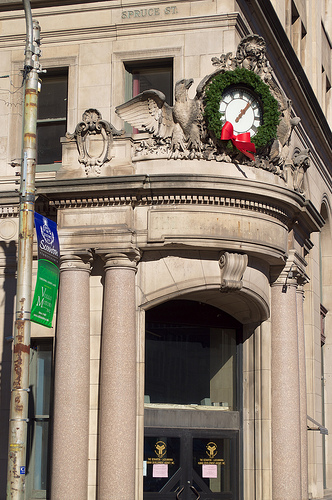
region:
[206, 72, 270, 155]
Christmas wreath on clock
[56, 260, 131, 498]
columns on the building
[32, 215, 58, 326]
blue and green banners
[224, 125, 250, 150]
red bow on wreath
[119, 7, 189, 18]
name of the street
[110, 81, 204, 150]
eagle statue on building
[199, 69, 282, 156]
The wreath around the clock.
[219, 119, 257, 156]
The red bow around the wreath.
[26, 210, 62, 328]
The blue and green banner hanging on the pole.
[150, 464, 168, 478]
The pink paper on the left side of the door.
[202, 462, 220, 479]
The pink paper on the right side of the door.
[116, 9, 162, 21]
The word SPRUCE on the building.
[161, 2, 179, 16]
The letters ST. on the building.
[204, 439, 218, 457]
The gold emblem on the right door.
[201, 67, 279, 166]
wreath around the clock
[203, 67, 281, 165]
wreath on clock is green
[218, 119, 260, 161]
attached bow is red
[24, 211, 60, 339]
banner attached to bowl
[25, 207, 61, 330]
banner on pole is green and blue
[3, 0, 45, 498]
pole is rusty and silver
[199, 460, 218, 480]
paper attached to right door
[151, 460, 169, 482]
paper attached to left door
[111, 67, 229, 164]
eagle statue by clock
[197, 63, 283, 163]
A round green wreath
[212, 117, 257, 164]
The ribbon is red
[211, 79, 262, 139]
Roman numerals on a clock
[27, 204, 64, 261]
A blue sign with white writing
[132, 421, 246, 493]
Two doors of a building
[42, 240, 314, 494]
Four columns of a building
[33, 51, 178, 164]
Two windows of a building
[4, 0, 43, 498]
A pole is tall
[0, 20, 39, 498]
a rusted metal pole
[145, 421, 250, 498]
glass doors to a building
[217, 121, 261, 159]
a red ribbon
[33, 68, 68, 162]
glass window on the building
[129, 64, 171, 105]
glass window on the building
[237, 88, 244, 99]
black roman numeral on clock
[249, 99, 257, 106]
black roman numeral on clock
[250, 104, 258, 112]
black roman numeral on clock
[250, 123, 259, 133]
black roman numeral on clock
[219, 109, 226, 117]
black roman numeral on clock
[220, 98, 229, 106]
black roman numeral on clock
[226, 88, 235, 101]
black roman numeral on clock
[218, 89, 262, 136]
black roman numerals on clock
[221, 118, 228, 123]
black roman numeral on clock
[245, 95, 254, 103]
black roman numeral on clock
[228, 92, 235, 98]
black roman numeral on clock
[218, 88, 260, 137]
black romans numeral on clock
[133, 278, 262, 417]
A window on a building.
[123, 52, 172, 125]
A window on a building.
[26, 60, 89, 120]
A window on a building.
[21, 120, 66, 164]
A window on a building.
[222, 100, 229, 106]
A number on the clock.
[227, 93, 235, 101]
A number on the clock.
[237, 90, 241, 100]
A number on the clock.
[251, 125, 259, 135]
A number on the clock.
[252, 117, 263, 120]
A number on the clock.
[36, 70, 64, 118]
a window on a building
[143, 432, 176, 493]
a window on a building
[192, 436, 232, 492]
a window on a building